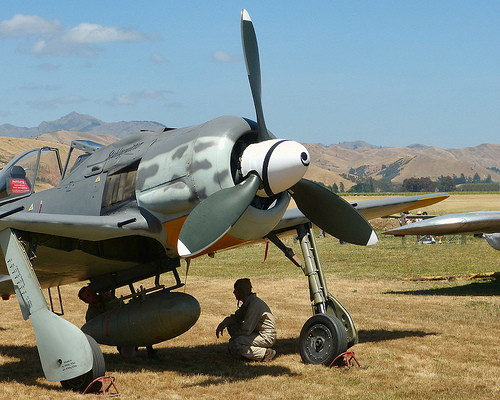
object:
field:
[0, 183, 500, 400]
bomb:
[81, 291, 201, 346]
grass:
[0, 192, 500, 400]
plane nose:
[240, 139, 312, 199]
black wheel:
[298, 314, 348, 366]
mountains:
[0, 112, 500, 207]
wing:
[238, 192, 451, 248]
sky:
[0, 0, 500, 148]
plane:
[381, 208, 500, 252]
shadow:
[381, 271, 500, 297]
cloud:
[0, 0, 237, 121]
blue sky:
[0, 0, 500, 152]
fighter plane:
[0, 9, 453, 391]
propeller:
[175, 7, 381, 261]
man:
[216, 277, 277, 362]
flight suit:
[221, 292, 280, 359]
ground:
[0, 186, 500, 400]